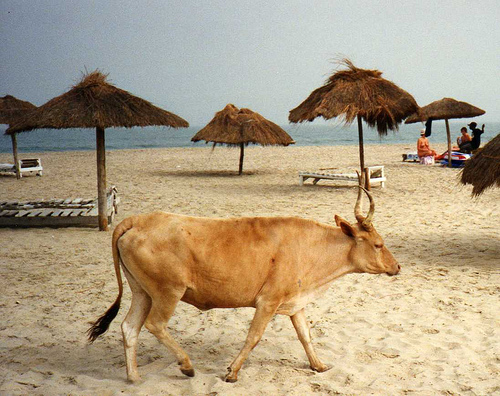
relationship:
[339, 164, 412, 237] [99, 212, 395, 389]
horns on cow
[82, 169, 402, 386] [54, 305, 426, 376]
cow on sand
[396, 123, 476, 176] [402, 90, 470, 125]
people under umbrella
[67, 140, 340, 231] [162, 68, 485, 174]
beach with umbrella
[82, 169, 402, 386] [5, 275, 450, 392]
cow on beach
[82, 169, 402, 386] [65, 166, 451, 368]
cow on beach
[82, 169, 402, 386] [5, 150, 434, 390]
cow on beach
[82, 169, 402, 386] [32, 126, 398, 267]
cow on beach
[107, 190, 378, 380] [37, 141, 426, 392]
cow on beach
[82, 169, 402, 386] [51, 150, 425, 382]
cow on beach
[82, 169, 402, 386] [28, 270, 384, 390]
cow on beach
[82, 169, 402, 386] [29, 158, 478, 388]
cow on beach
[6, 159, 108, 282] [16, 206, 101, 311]
chairs on sand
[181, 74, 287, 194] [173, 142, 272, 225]
umbrellas on beach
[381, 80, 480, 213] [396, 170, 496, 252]
people on beach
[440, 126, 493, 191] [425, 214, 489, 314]
umbrella on sand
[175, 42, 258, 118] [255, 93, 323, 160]
sky above water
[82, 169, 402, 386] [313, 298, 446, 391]
cow walking on beach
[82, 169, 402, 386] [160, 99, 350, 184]
cow on a beach